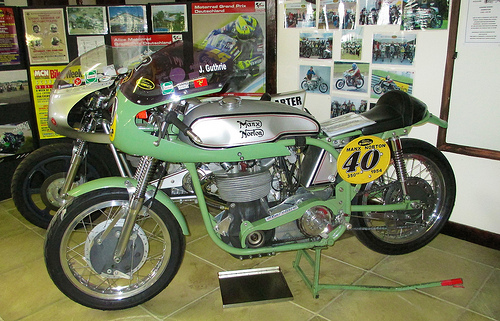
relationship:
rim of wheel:
[397, 135, 462, 172] [345, 125, 484, 275]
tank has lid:
[210, 164, 293, 207] [228, 161, 240, 170]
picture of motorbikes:
[278, 4, 316, 31] [298, 38, 334, 62]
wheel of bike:
[345, 125, 484, 275] [25, 41, 468, 304]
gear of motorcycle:
[169, 109, 187, 134] [41, 39, 463, 313]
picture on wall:
[278, 4, 316, 31] [249, 12, 467, 172]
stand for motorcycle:
[306, 256, 470, 306] [90, 39, 448, 282]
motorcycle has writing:
[90, 39, 448, 282] [229, 111, 288, 166]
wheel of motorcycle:
[345, 125, 484, 275] [90, 39, 448, 282]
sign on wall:
[195, 5, 277, 126] [249, 12, 467, 172]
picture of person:
[278, 4, 316, 31] [224, 15, 288, 76]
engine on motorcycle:
[303, 142, 347, 205] [41, 39, 463, 313]